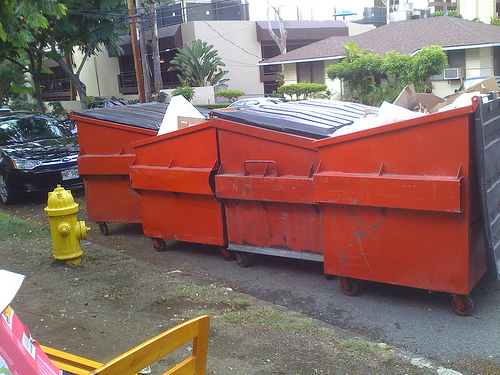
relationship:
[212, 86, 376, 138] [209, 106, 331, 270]
cover on bin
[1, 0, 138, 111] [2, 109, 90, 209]
tree behind car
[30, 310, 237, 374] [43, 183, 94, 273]
chair near hydrant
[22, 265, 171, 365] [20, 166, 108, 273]
ground around hydrant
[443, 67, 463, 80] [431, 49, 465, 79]
ac in window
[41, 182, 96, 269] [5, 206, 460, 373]
hydrant by curb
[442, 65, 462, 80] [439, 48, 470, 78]
air conditioner in window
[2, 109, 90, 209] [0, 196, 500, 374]
car on paved street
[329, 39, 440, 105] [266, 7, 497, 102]
tree in front of house